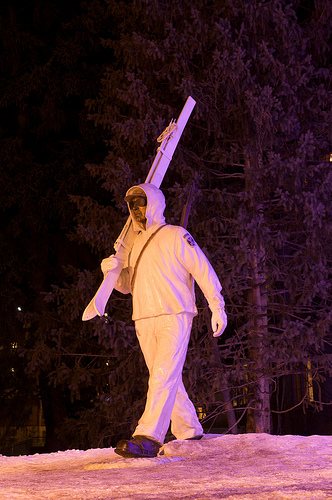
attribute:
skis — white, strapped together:
[143, 96, 201, 186]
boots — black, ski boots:
[114, 434, 159, 459]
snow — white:
[1, 453, 332, 500]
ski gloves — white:
[211, 310, 227, 337]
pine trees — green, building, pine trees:
[196, 0, 331, 435]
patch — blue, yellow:
[181, 233, 197, 249]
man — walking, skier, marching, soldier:
[101, 183, 229, 458]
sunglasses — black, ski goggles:
[128, 197, 147, 208]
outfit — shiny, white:
[99, 182, 228, 438]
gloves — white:
[208, 309, 229, 337]